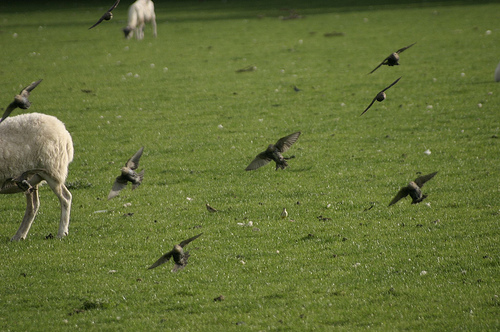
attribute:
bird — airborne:
[86, 3, 123, 26]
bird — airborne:
[2, 71, 50, 121]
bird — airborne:
[107, 147, 147, 197]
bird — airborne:
[145, 228, 201, 278]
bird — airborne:
[244, 127, 307, 178]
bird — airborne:
[357, 76, 405, 113]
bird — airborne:
[387, 170, 437, 210]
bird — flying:
[1, 71, 43, 121]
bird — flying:
[103, 145, 148, 195]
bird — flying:
[143, 229, 208, 274]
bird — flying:
[384, 169, 442, 211]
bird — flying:
[353, 73, 406, 119]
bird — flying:
[365, 41, 418, 75]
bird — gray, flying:
[245, 130, 302, 172]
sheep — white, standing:
[5, 114, 76, 240]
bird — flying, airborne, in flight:
[367, 44, 414, 75]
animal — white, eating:
[123, 3, 160, 40]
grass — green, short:
[1, 3, 498, 331]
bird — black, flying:
[89, 1, 120, 29]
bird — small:
[147, 233, 201, 268]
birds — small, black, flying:
[3, 3, 439, 269]